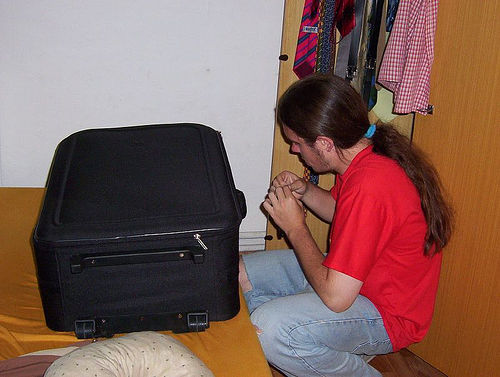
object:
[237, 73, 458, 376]
man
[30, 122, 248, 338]
luggage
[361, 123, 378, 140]
band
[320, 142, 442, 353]
shirt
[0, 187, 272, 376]
table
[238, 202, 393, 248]
jeans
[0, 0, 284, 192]
wall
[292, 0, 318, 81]
ties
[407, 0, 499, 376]
door